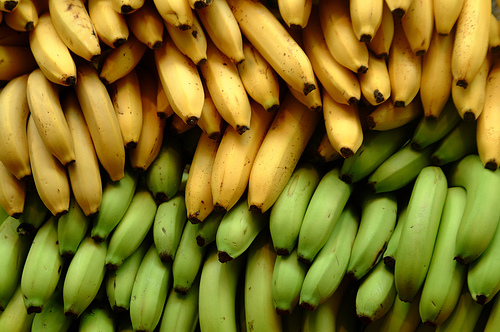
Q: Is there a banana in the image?
A: Yes, there are bananas.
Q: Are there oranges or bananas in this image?
A: Yes, there are bananas.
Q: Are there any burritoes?
A: No, there are no burritoes.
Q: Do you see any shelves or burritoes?
A: No, there are no burritoes or shelves.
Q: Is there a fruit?
A: Yes, there is a fruit.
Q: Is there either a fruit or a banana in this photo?
A: Yes, there is a fruit.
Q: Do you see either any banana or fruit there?
A: Yes, there is a fruit.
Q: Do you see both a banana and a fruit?
A: Yes, there are both a fruit and a banana.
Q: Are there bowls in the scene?
A: No, there are no bowls.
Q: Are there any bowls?
A: No, there are no bowls.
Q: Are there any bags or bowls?
A: No, there are no bowls or bags.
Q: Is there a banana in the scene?
A: Yes, there is a banana.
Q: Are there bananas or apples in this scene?
A: Yes, there is a banana.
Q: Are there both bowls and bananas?
A: No, there is a banana but no bowls.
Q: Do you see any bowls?
A: No, there are no bowls.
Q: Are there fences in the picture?
A: No, there are no fences.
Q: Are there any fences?
A: No, there are no fences.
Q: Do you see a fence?
A: No, there are no fences.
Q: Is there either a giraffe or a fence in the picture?
A: No, there are no fences or giraffes.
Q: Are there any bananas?
A: Yes, there is a banana.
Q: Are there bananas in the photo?
A: Yes, there is a banana.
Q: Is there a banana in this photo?
A: Yes, there is a banana.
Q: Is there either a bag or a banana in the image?
A: Yes, there is a banana.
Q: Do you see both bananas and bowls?
A: No, there is a banana but no bowls.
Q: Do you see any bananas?
A: Yes, there are bananas.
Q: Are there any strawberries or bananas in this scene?
A: Yes, there are bananas.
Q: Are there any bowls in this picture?
A: No, there are no bowls.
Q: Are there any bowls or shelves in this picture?
A: No, there are no bowls or shelves.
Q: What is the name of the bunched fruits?
A: The fruits are bananas.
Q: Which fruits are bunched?
A: The fruits are bananas.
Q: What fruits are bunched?
A: The fruits are bananas.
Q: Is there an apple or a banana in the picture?
A: Yes, there are bananas.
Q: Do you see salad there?
A: No, there is no salad.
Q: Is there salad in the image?
A: No, there is no salad.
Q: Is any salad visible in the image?
A: No, there is no salad.